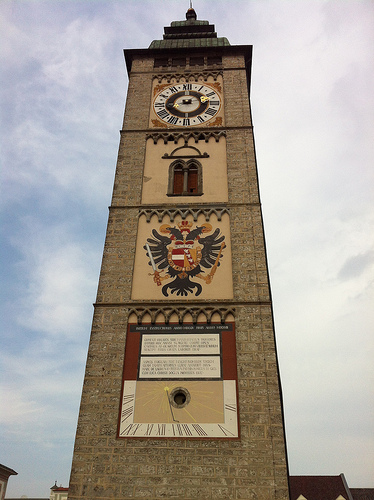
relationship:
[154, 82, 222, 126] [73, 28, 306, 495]
clock on building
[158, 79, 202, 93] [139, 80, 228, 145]
numbers on clock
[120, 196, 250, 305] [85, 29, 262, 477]
mural on tower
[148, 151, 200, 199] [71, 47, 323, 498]
windows on tower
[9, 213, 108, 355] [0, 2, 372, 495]
cloud in sky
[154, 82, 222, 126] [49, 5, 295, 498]
clock on tower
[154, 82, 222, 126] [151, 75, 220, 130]
clock has roman numerals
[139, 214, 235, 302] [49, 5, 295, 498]
bird diety on tower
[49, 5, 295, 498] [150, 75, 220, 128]
tower with clock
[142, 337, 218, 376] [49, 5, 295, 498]
words on tower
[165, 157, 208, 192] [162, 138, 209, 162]
double door under arch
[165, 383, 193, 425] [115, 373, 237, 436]
image on plaque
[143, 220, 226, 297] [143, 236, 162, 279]
shield with sword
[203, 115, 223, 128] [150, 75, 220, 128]
creature in corner of clock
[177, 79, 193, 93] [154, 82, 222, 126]
roman numeral on clock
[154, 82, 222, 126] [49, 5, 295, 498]
clock at top of tower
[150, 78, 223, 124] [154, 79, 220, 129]
clock with roman numerals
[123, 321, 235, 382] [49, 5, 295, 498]
plaque on tower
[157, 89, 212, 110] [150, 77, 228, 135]
hands on clock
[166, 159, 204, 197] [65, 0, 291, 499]
windows on tower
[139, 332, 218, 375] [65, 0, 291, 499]
words on tower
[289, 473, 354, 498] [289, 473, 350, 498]
rooftop on building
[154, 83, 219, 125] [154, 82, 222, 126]
roman numerals on clock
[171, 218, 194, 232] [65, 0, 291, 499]
crown drawn on tower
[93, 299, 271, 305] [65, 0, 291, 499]
ridge on tower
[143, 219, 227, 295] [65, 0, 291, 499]
shield on tower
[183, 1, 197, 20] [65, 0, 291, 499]
peak on tower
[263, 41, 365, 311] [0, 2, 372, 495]
clouds in sky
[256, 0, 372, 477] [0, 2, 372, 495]
clouds in sky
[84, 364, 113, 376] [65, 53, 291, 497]
stone in a wall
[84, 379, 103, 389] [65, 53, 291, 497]
stone in a wall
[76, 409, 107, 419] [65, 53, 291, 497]
stone in a wall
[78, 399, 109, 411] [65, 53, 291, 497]
stone in a wall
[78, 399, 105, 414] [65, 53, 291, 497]
stone in a wall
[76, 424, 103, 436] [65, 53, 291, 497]
stone in a wall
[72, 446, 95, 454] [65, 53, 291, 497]
stone in a wall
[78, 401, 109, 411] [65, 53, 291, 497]
stone in a wall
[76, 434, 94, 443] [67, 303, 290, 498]
stone in a wall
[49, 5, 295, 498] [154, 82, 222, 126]
tower has clock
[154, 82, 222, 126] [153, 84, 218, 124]
clock has face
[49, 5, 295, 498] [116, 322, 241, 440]
tower has sign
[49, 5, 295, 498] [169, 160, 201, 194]
tower has window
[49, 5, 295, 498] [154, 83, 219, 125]
tower has roman numerals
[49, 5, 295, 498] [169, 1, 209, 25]
tower has steeple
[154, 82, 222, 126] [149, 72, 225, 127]
clock has trim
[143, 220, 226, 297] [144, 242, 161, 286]
shield has sword